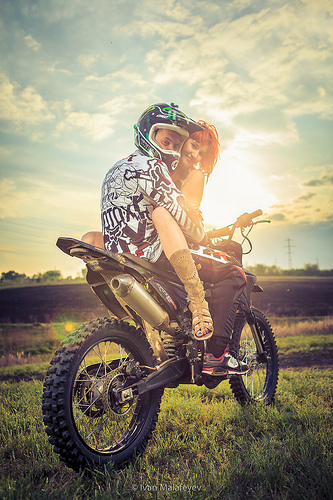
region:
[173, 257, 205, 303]
the boot is brown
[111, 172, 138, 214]
the shirt is black and white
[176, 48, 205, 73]
the clouds are white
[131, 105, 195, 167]
the helmet is black and green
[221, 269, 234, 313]
the pants are black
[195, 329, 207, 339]
the polish is blue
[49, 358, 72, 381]
the tire is black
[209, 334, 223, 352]
the sock is black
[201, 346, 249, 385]
the shoe is black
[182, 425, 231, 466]
the grass is green in color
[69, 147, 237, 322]
Man and woman on a motorcycle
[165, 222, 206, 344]
woman wearing brown boots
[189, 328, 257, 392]
man wearing sneakers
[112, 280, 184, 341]
Motorcycle with chrome pipe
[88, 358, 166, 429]
motorcycle with a chain on it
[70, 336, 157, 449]
wheel with chrome spokes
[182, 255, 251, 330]
man wearing black pants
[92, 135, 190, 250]
Man wearing a white shirt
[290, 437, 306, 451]
patch of green grass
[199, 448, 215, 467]
patch of green grass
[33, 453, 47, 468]
patch of green grass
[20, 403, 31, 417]
patch of green grass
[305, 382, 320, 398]
patch of green grass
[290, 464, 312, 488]
patch of green grass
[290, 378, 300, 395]
patch of green grass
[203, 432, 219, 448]
patch of green grass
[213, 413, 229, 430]
patch of green grass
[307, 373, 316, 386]
patch of green grass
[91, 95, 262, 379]
Two people in the foreground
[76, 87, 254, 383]
A man and a woman in the foreground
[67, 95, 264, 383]
Man and woman are holding each other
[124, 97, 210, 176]
Man is wearing a helmet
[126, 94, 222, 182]
Man and woman are looking at the camera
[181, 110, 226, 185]
Woman has red hair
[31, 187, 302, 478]
Man and woman are on a motorbike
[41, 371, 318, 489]
Motorbike is in the grass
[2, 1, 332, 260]
Clouds are in the sky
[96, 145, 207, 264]
Man is wearing a white shirt with graphic designs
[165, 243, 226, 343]
girl wearing tall shoes on left foot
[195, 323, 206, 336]
girl has blue toenail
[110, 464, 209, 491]
name written on bottom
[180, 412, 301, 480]
green grass on ground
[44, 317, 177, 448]
large black knobby tire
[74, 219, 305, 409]
large dirtbike/motorcycle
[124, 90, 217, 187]
man wearing green helmet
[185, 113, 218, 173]
girl with red hair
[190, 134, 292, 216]
bright sun in back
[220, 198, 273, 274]
part of handle of bike